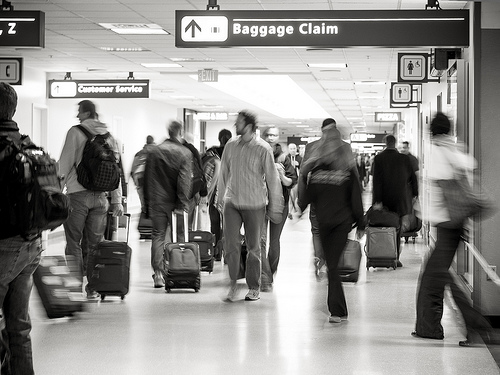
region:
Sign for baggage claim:
[175, 10, 470, 50]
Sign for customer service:
[46, 78, 148, 98]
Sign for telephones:
[0, 58, 20, 85]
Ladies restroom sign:
[399, 53, 426, 80]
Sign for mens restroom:
[392, 83, 411, 105]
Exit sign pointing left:
[198, 69, 219, 84]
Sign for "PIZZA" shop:
[374, 111, 401, 122]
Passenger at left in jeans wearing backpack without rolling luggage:
[0, 82, 67, 372]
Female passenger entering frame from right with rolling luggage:
[417, 110, 497, 367]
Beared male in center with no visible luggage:
[217, 109, 287, 306]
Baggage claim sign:
[176, 10, 354, 52]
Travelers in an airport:
[148, 104, 294, 329]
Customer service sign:
[42, 71, 155, 106]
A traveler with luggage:
[56, 99, 149, 310]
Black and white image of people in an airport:
[63, 83, 430, 331]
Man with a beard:
[211, 101, 285, 317]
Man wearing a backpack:
[57, 97, 131, 234]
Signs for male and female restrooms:
[376, 48, 442, 122]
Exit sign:
[188, 62, 235, 87]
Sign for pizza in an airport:
[361, 106, 421, 134]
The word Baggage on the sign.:
[224, 12, 299, 41]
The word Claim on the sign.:
[297, 17, 340, 37]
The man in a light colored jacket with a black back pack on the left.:
[74, 124, 124, 188]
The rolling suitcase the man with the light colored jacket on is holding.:
[98, 202, 132, 304]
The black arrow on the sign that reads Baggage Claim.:
[182, 20, 204, 37]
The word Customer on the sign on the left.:
[76, 83, 116, 94]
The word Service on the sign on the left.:
[114, 85, 143, 95]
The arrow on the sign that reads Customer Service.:
[51, 83, 63, 95]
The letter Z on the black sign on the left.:
[4, 16, 20, 37]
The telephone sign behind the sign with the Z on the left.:
[2, 62, 19, 79]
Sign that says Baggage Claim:
[231, 20, 351, 40]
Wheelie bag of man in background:
[160, 236, 204, 288]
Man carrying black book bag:
[78, 137, 123, 191]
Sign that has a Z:
[6, 20, 24, 40]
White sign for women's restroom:
[400, 57, 424, 79]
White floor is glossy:
[108, 298, 449, 373]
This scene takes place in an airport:
[5, 7, 495, 373]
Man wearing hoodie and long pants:
[426, 110, 486, 221]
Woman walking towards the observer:
[311, 105, 368, 327]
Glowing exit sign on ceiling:
[191, 64, 223, 84]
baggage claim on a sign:
[232, 20, 350, 39]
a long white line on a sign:
[230, 13, 475, 25]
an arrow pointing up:
[185, 17, 199, 38]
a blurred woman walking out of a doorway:
[421, 110, 494, 361]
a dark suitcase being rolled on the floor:
[159, 211, 201, 296]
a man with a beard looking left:
[222, 105, 266, 164]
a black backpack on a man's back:
[71, 126, 115, 189]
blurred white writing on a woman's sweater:
[306, 167, 353, 187]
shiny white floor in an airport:
[139, 297, 214, 357]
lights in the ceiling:
[309, 54, 347, 79]